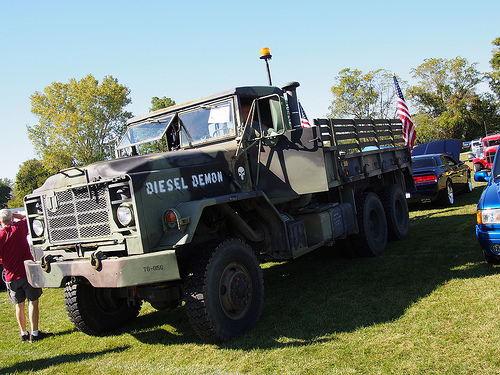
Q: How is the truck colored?
A: Army colors.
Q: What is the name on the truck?
A: Diesel demon.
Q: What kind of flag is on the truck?
A: American flag.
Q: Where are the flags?
A: On the back of the truck.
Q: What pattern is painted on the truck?
A: Camouflage.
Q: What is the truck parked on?
A: Grass.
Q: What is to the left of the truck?
A: A person.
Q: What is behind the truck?
A: A black car.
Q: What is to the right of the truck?
A: A blue car.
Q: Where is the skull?
A: On the side of the truck.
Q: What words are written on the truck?
A: "Diesel Demon".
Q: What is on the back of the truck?
A: Two flags.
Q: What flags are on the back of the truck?
A: United States flags.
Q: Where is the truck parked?
A: On a grassy field.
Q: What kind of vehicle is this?
A: A Diesel Demon.